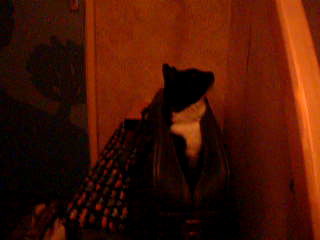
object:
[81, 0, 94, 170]
frame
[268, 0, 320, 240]
rail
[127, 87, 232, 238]
bag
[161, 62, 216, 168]
cat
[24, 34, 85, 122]
tree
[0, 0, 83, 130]
wall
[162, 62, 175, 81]
ear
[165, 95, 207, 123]
neck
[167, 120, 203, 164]
chest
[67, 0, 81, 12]
thermostat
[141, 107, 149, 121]
strap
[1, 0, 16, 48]
spot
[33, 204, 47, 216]
items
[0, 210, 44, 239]
table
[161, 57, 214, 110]
head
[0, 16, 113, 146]
background